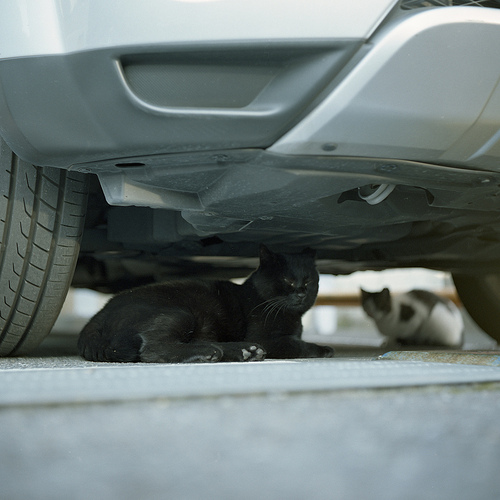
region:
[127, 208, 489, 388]
two cats under car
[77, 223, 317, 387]
black cat under car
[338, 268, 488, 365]
black and white cat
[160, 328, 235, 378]
cat has black paws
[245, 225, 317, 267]
cat has black ears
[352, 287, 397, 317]
cat has dark ears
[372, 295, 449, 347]
dark spots on cat's back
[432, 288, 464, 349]
cat has white back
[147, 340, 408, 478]
pavement is light grey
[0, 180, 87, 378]
black tire on car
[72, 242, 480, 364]
Cats under a car.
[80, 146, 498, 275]
Underside of a car.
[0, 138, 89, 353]
Black tire on the car.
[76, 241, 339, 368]
Black hair on the cat.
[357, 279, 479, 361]
Brown and white cat.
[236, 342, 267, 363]
bottom pad on cat's paw.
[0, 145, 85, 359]
Tread on the tire.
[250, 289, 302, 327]
white whiskers on the cat.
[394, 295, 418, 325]
Spot on the cat.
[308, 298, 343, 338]
White bucket on the ground.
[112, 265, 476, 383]
cats are under car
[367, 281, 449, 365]
grey and white cat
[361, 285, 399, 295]
cat has grey ears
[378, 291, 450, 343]
grey spots on back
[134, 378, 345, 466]
pavement is light grey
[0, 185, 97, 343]
car wheel is brown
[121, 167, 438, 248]
grey undercarriage on car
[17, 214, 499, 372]
Two cats under a car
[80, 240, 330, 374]
A black cat sitting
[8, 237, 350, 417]
A black cat sitting under a car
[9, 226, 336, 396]
A black cat sitting next to a car tire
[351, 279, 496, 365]
Blurry black and white cat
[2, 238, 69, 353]
Part of a car tire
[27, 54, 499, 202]
Bottom part of a car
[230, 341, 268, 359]
The bottom of a cat's paw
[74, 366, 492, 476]
Part of a parking lot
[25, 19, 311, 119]
Bottom part of a car bumper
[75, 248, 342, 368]
a black cat sitting under a car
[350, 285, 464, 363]
a white and brown cat sitting down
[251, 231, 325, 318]
the head of a black cat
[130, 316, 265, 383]
the hind legs of a black cat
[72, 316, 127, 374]
the tail of a black cat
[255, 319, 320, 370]
the front paws of a black cat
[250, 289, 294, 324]
the white whiskers of a black cat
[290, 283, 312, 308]
the nose of a black cat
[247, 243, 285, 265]
the ears of a black cat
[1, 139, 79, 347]
the tire of a car